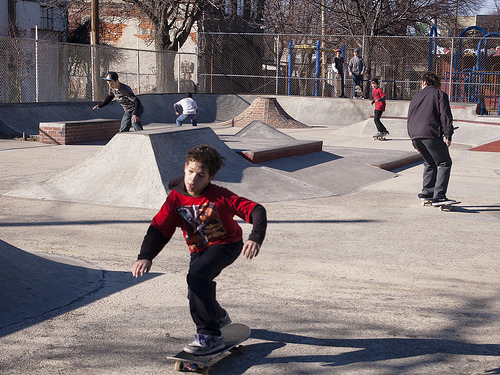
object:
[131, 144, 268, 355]
boy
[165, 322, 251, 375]
skateboard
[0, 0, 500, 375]
park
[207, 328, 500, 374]
shadow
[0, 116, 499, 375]
ground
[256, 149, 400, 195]
ramp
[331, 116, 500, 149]
ramp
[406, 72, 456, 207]
man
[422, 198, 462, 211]
skateboard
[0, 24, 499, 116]
fence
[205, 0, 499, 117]
playground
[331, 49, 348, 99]
boy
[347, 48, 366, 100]
boy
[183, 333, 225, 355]
foot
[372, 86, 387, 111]
shirt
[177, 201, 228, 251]
cartoons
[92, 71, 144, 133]
person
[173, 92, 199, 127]
person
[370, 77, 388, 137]
person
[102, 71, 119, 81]
hat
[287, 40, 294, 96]
pole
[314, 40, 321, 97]
pole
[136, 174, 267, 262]
hoodie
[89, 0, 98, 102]
pole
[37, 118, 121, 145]
bench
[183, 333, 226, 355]
shoe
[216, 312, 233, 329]
shoe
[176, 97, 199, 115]
t-shirt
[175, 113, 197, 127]
jeans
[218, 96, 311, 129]
half pipe section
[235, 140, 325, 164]
grinding wall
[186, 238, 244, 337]
pants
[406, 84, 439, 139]
back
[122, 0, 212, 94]
tree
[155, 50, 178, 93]
trunk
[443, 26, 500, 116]
equipment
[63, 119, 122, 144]
grind rail